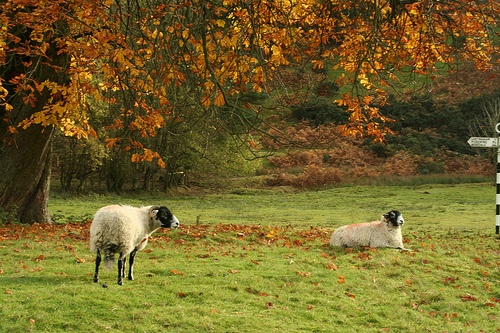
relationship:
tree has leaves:
[0, 0, 499, 223] [8, 7, 497, 163]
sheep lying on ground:
[330, 210, 406, 248] [0, 179, 499, 331]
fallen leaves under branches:
[186, 219, 319, 261] [186, 0, 337, 110]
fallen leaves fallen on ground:
[170, 269, 185, 275] [172, 263, 322, 328]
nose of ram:
[170, 217, 186, 230] [88, 202, 179, 283]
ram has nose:
[88, 202, 179, 283] [170, 217, 186, 230]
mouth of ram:
[168, 226, 181, 233] [88, 202, 179, 283]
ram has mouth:
[88, 202, 179, 283] [168, 226, 181, 233]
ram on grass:
[88, 202, 179, 283] [64, 289, 175, 329]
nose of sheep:
[399, 215, 406, 229] [330, 210, 406, 248]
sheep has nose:
[330, 210, 406, 248] [399, 215, 406, 229]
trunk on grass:
[10, 65, 108, 251] [35, 201, 238, 321]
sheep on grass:
[330, 210, 406, 248] [255, 185, 471, 303]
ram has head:
[88, 204, 181, 285] [146, 198, 180, 236]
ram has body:
[88, 204, 181, 285] [84, 198, 153, 250]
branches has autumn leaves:
[6, 0, 498, 158] [81, 18, 419, 88]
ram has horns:
[88, 204, 181, 285] [144, 202, 162, 220]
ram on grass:
[88, 204, 181, 285] [26, 238, 238, 328]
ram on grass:
[88, 204, 181, 285] [21, 247, 213, 325]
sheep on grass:
[79, 191, 409, 292] [59, 184, 464, 327]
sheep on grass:
[79, 191, 409, 292] [46, 189, 478, 314]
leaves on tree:
[8, 7, 497, 163] [4, 4, 113, 227]